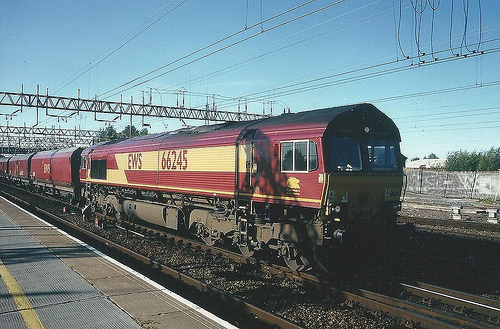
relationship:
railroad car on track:
[1, 104, 413, 275] [354, 281, 495, 329]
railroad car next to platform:
[1, 104, 413, 275] [2, 195, 226, 321]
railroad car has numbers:
[1, 104, 413, 275] [161, 150, 187, 168]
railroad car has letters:
[1, 104, 413, 275] [128, 153, 143, 169]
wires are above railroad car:
[52, 1, 499, 128] [1, 104, 413, 275]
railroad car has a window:
[1, 104, 413, 275] [280, 138, 308, 172]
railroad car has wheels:
[1, 104, 413, 275] [280, 249, 308, 272]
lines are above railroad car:
[56, 2, 500, 134] [1, 104, 413, 275]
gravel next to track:
[0, 182, 497, 321] [354, 281, 495, 329]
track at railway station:
[1, 182, 495, 321] [4, 170, 500, 329]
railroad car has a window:
[1, 104, 413, 275] [325, 138, 362, 172]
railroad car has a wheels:
[1, 104, 413, 275] [280, 249, 308, 272]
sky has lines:
[1, 3, 498, 157] [56, 2, 500, 134]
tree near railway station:
[443, 146, 499, 170] [4, 82, 499, 320]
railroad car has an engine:
[1, 104, 413, 275] [81, 118, 257, 211]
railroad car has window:
[1, 104, 413, 275] [280, 138, 308, 172]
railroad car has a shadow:
[1, 104, 413, 275] [357, 227, 500, 296]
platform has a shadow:
[2, 195, 226, 321] [3, 191, 262, 321]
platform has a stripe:
[2, 195, 226, 321] [78, 176, 323, 205]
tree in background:
[443, 146, 499, 170] [0, 2, 498, 169]